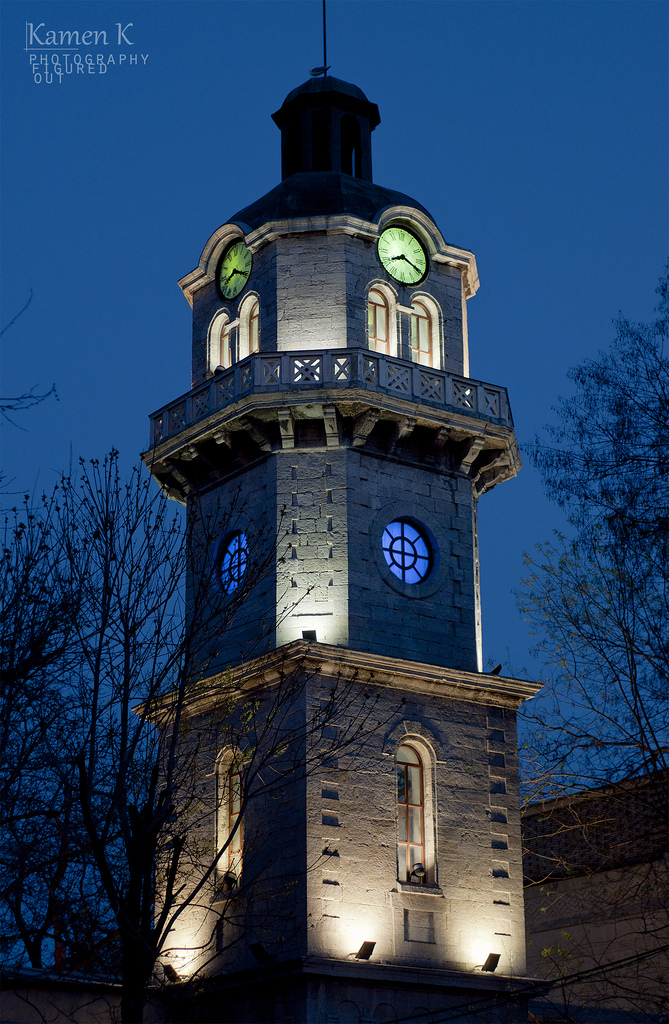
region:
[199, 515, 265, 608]
blue circular window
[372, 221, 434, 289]
green analog clock face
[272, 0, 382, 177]
bird on top of tower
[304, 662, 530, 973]
dual lit rectangular wall and window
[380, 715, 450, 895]
small round light mounted in window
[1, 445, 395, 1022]
tree branches without leaves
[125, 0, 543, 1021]
multi-story clock tower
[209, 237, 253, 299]
green clock face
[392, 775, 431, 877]
window on the building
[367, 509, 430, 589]
window on the building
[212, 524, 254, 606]
window on the building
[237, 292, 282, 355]
window on the building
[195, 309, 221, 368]
window on the building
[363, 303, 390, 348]
window on the building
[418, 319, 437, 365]
window on the building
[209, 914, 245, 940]
window on the building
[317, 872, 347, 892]
square on the building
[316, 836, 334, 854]
square on the building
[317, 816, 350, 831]
square on the building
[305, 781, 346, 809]
square on the building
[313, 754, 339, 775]
square on the building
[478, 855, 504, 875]
square on the building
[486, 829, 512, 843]
square on the building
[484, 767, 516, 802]
square on the building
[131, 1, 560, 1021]
an ornate lit up click tower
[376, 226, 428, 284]
a green clock face with black numbers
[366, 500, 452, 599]
a round blue lighted window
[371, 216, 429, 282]
clock on a tower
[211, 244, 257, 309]
clock on a tower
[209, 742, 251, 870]
window on a building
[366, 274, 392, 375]
window on a building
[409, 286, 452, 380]
window on a building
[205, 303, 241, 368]
window on a building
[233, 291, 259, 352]
window on a building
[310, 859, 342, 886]
square in a tower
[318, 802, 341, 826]
square in a tower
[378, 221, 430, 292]
round green clock in right side of clock tower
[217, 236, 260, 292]
round green clock in left side of clock tower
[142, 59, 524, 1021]
large iluminated clock tower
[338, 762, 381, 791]
A stone in a wall.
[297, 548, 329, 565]
A stone in a wall.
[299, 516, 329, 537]
A stone in a wall.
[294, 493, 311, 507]
A stone in a wall.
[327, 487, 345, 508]
A stone in a wall.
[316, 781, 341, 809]
A stone in a wall.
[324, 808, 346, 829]
A stone in a wall.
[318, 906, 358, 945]
A stone in a wall.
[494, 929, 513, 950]
stone block on tower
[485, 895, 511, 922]
stone block on tower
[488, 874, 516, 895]
stone block on tower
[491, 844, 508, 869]
stone block on tower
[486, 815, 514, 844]
stone block on tower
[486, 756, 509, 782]
stone block on tower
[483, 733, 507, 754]
stone block on tower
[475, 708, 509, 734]
stone block on tower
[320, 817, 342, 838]
stone block on tower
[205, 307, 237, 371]
a window on a building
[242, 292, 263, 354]
a window on a building